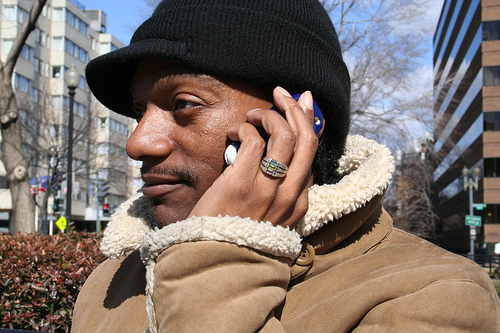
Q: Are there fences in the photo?
A: No, there are no fences.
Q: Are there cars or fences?
A: No, there are no fences or cars.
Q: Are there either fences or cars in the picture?
A: No, there are no fences or cars.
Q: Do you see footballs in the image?
A: No, there are no footballs.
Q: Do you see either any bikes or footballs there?
A: No, there are no footballs or bikes.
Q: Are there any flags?
A: No, there are no flags.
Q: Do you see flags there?
A: No, there are no flags.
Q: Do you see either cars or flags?
A: No, there are no flags or cars.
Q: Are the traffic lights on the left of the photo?
A: Yes, the traffic lights are on the left of the image.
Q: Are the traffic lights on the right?
A: No, the traffic lights are on the left of the image.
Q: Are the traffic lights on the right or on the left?
A: The traffic lights are on the left of the image.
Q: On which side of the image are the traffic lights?
A: The traffic lights are on the left of the image.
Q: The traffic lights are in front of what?
A: The traffic lights are in front of the building.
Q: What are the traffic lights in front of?
A: The traffic lights are in front of the building.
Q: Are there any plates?
A: No, there are no plates.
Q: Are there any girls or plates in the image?
A: No, there are no plates or girls.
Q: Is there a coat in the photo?
A: Yes, there is a coat.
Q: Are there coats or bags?
A: Yes, there is a coat.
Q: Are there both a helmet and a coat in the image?
A: No, there is a coat but no helmets.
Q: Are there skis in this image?
A: No, there are no skis.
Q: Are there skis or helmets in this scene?
A: No, there are no skis or helmets.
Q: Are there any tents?
A: No, there are no tents.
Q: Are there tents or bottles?
A: No, there are no tents or bottles.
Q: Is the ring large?
A: Yes, the ring is large.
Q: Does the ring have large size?
A: Yes, the ring is large.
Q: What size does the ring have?
A: The ring has large size.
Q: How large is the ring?
A: The ring is large.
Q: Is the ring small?
A: No, the ring is large.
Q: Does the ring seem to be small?
A: No, the ring is large.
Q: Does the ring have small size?
A: No, the ring is large.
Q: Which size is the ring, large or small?
A: The ring is large.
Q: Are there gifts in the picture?
A: No, there are no gifts.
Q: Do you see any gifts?
A: No, there are no gifts.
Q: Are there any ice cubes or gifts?
A: No, there are no gifts or ice cubes.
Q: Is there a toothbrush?
A: No, there are no toothbrushes.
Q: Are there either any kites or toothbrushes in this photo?
A: No, there are no toothbrushes or kites.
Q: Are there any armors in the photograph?
A: No, there are no armors.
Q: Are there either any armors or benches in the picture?
A: No, there are no armors or benches.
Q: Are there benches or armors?
A: No, there are no armors or benches.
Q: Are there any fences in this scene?
A: No, there are no fences.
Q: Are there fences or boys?
A: No, there are no fences or boys.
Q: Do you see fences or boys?
A: No, there are no fences or boys.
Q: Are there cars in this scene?
A: No, there are no cars.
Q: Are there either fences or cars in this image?
A: No, there are no cars or fences.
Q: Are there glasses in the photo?
A: No, there are no glasses.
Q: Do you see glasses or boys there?
A: No, there are no glasses or boys.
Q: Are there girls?
A: No, there are no girls.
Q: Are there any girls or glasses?
A: No, there are no girls or glasses.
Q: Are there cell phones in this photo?
A: Yes, there is a cell phone.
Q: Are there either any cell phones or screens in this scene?
A: Yes, there is a cell phone.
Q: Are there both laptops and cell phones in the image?
A: No, there is a cell phone but no laptops.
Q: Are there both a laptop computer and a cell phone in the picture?
A: No, there is a cell phone but no laptops.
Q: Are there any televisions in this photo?
A: No, there are no televisions.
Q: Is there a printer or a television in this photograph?
A: No, there are no televisions or printers.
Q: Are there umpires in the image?
A: No, there are no umpires.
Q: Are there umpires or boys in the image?
A: No, there are no umpires or boys.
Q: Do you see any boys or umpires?
A: No, there are no umpires or boys.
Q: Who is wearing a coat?
A: The man is wearing a coat.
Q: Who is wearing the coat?
A: The man is wearing a coat.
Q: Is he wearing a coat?
A: Yes, the man is wearing a coat.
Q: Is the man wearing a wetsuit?
A: No, the man is wearing a coat.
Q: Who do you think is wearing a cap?
A: The man is wearing a cap.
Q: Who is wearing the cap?
A: The man is wearing a cap.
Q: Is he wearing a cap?
A: Yes, the man is wearing a cap.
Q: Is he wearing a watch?
A: No, the man is wearing a cap.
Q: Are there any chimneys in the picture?
A: No, there are no chimneys.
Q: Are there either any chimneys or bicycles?
A: No, there are no chimneys or bicycles.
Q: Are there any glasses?
A: No, there are no glasses.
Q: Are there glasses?
A: No, there are no glasses.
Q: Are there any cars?
A: No, there are no cars.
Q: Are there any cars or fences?
A: No, there are no cars or fences.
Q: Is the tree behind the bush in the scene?
A: Yes, the tree is behind the bush.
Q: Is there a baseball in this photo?
A: No, there are no baseballs.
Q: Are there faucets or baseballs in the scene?
A: No, there are no baseballs or faucets.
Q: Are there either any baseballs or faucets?
A: No, there are no baseballs or faucets.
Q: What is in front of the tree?
A: The bush is in front of the tree.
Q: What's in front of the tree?
A: The bush is in front of the tree.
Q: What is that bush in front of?
A: The bush is in front of the tree.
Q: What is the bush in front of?
A: The bush is in front of the tree.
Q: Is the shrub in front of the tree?
A: Yes, the shrub is in front of the tree.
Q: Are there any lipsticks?
A: No, there are no lipsticks.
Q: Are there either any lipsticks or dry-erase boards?
A: No, there are no lipsticks or dry-erase boards.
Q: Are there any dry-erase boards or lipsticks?
A: No, there are no lipsticks or dry-erase boards.